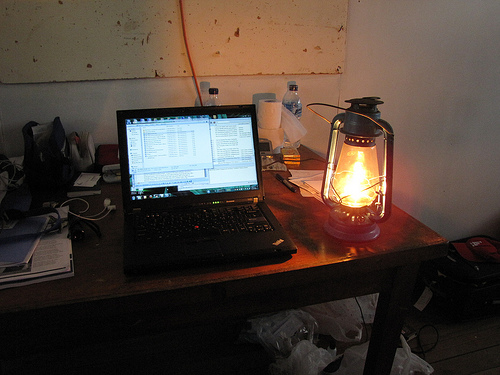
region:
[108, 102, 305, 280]
black laptop with keyboard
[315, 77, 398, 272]
black lantern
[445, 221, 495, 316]
black luggage for personal belongings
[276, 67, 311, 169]
drinking water for consumption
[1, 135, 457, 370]
brown wooden desk for office work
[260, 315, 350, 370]
white plastic bag for groceries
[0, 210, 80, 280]
book for learning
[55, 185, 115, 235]
white cord for charging an electronic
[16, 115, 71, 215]
blue lunch box for meals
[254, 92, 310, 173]
toilet paper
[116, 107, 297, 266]
black laptop on the desk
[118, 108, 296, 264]
powered on black laptop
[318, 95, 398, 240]
lit lantern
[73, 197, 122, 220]
white usb cord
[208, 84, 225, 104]
bottle with a blue top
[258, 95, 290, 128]
roll of white paper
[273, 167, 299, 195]
black writing instrument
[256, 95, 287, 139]
two rolls of paper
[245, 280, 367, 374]
bunch of plastic bags under the table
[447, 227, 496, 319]
red and black suitcase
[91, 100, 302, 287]
A black laptop.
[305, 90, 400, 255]
A lantern.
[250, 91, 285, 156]
Two rolls of toilet paper stacked on top of one another.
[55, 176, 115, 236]
A pair of earbuds.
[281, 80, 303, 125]
A plastic bottle.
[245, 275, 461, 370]
Several bags are on the floor.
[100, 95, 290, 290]
The laptop is being used by someone.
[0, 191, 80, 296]
A stack of papers.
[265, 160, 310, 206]
A pen is on the desk.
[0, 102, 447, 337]
A large wooden desk.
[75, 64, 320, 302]
black lap top on table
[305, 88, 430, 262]
lantern on the table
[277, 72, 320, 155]
water bottle on the table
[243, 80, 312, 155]
toilet roll on the table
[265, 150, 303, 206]
pen on the table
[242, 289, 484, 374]
white plastic bags under the desk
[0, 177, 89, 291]
books on the table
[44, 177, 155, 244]
white cord on table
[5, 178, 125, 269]
black cord on the table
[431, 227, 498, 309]
black and red bag on the floor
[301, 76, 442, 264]
A black lantern is lit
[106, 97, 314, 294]
The screen of a black computer is on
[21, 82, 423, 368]
The desk is made of wood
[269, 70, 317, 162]
A water bottle is on top of the desk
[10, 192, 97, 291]
A stack of blue and white papers sits next to the laptop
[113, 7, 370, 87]
A chipped white board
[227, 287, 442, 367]
Plastic bags underneath the desk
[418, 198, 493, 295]
A red and black bag with a white logo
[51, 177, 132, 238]
A white charger cable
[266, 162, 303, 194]
A grey and black pen